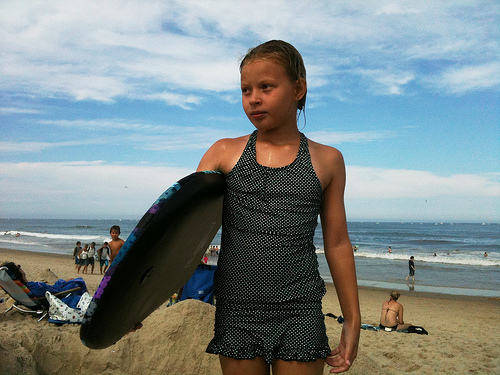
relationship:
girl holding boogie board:
[130, 40, 362, 374] [80, 170, 226, 350]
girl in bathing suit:
[130, 40, 362, 374] [205, 130, 331, 365]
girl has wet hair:
[130, 40, 362, 374] [240, 40, 307, 131]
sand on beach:
[1, 248, 499, 374] [0, 0, 499, 374]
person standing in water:
[406, 256, 417, 282] [1, 218, 500, 290]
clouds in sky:
[1, 0, 500, 224] [1, 1, 500, 225]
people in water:
[0, 219, 500, 283] [1, 218, 500, 290]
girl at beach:
[130, 40, 363, 375] [0, 0, 499, 374]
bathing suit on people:
[379, 307, 400, 332] [377, 288, 410, 332]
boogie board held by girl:
[80, 170, 226, 350] [130, 40, 362, 374]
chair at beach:
[0, 265, 81, 321] [0, 0, 499, 374]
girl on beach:
[130, 40, 362, 374] [0, 0, 499, 374]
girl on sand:
[130, 40, 362, 374] [1, 248, 499, 374]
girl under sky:
[130, 40, 362, 374] [1, 1, 500, 225]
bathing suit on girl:
[205, 130, 331, 365] [130, 40, 362, 374]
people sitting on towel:
[377, 288, 410, 332] [360, 321, 428, 335]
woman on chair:
[1, 259, 88, 298] [0, 265, 81, 321]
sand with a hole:
[1, 248, 499, 374] [5, 301, 226, 374]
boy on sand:
[107, 226, 127, 261] [1, 248, 499, 374]